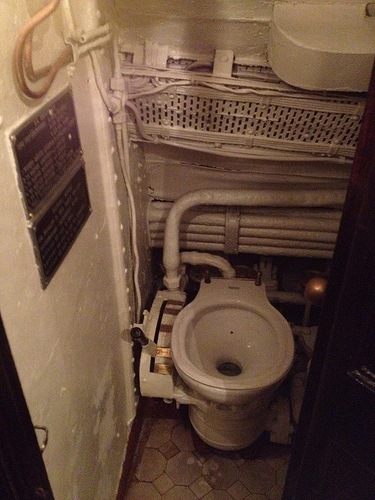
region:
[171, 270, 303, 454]
the bottom portion of a toilet sits in this room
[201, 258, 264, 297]
the toilet has no tank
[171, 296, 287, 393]
the toilet does not have a lid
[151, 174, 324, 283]
several pipes are behind the toilet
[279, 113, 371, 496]
the door for the room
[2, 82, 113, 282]
a sign on the wall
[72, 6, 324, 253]
everything is painted white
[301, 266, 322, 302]
the door knob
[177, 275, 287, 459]
the bowl for the toilet is white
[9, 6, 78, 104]
copper wire runs through the wall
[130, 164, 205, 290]
the pipe is white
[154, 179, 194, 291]
the pipe is white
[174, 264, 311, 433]
the toilet is white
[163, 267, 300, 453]
White porcelain toilet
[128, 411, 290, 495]
Dirty beige bathroom tile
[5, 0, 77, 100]
exposed copper piping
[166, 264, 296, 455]
toilet with no lid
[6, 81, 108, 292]
plaque on side of wall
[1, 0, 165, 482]
white wall in bathroom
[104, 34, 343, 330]
white wires running along wall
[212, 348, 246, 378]
hole in toilet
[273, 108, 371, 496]
open door leading to bathroom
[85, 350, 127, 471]
lighter patch of wall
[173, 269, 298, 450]
a white toilet bowl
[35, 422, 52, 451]
a metal handle on a door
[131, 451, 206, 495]
brown tile on the floor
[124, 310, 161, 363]
a handle beside the toilet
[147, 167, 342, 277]
white pipes on the wall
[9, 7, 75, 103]
a copper pipe on the wall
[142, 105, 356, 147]
a white screen on the wall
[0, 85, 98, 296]
a sign on the wall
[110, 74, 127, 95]
a pipe fitting on the pipe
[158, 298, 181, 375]
copper plate by the toilet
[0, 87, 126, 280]
a black note on the wall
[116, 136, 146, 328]
the wires are white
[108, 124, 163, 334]
the wires are white